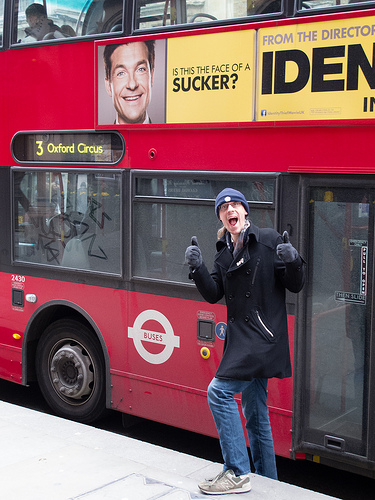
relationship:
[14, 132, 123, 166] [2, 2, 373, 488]
sign on bus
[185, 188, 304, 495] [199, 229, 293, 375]
man wearing coat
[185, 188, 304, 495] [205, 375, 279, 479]
man wearing jeans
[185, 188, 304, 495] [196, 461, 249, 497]
man wearing foot wear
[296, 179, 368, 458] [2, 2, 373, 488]
door on bus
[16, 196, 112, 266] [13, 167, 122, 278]
graffiti on window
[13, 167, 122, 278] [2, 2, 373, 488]
window on bus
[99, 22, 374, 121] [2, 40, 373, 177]
movie ad on side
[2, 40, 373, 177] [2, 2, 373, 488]
side of bus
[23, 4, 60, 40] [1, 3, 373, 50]
passenger on upper level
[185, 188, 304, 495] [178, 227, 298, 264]
man giving thumbs up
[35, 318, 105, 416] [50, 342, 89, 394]
tire with hubcap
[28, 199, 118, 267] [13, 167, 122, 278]
drawings are on window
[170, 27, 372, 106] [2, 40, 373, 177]
ad on side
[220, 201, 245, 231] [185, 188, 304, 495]
face of man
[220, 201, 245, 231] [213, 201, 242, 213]
face with eyes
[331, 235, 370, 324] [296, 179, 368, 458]
signs are on door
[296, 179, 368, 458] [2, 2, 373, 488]
door of bus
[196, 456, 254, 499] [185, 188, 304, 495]
shoe of man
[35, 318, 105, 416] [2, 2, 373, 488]
tire of bus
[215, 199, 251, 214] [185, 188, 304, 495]
eyeglasses of man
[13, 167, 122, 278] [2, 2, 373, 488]
window of bus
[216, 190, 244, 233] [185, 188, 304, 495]
head of man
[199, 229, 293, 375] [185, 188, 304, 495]
coat of man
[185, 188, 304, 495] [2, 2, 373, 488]
man exiting bus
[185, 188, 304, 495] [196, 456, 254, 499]
man wearing sneakers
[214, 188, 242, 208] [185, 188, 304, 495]
cap of man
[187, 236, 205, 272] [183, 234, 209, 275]
glove on hand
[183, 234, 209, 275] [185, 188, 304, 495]
hand of man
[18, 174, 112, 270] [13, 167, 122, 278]
writing of window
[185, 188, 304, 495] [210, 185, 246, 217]
man wearing hat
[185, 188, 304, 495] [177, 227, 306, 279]
man with gloves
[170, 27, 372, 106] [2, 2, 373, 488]
ad on bus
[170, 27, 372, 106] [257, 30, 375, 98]
ad with writing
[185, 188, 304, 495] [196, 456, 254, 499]
man with shoe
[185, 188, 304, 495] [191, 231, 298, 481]
man wearing attire